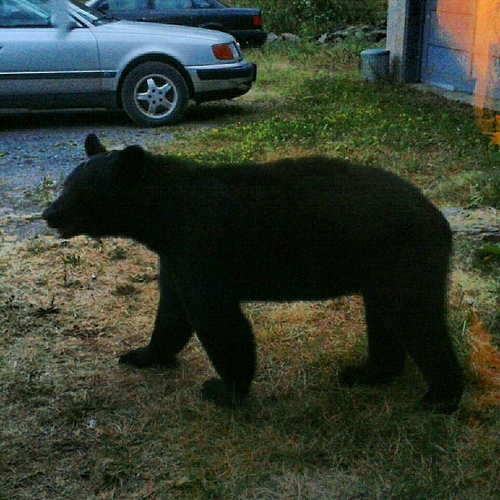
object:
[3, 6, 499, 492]
field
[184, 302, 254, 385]
leg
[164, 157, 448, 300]
side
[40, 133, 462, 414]
bear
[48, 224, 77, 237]
mouth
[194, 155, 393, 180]
back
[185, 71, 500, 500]
grass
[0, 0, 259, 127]
car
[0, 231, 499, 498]
patches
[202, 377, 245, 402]
paws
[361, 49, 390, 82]
cone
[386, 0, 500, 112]
garage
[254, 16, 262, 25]
light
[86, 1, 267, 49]
car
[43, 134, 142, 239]
head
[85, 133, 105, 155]
ear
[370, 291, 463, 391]
legs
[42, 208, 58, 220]
nose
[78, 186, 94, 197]
eye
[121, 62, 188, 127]
tire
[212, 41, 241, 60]
light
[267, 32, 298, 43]
rocks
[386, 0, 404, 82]
wall